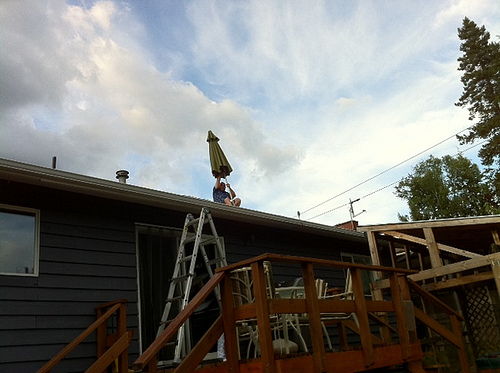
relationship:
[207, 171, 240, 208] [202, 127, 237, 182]
man holding umbrella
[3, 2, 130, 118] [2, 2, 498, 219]
clouds in sky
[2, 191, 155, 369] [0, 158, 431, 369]
wall of house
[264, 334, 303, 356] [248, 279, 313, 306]
box under table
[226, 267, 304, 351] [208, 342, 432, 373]
chair on floor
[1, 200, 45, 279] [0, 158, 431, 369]
window on house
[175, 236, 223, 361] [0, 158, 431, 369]
door for house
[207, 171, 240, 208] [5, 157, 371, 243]
man on roof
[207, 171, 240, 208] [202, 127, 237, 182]
man mounting umbrella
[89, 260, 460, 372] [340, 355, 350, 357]
deck made of wood